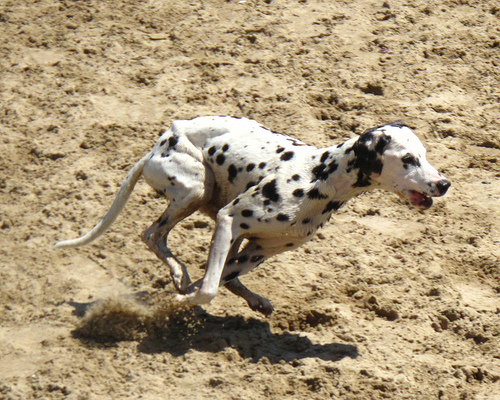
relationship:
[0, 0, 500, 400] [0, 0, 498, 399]
dirt on ground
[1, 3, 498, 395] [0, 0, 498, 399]
dirt on ground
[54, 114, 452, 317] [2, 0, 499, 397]
dog running on sand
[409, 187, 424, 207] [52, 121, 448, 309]
tongue of dog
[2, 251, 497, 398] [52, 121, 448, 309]
sand field under dog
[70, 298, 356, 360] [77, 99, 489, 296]
shadow of dog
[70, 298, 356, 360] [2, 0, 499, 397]
shadow on sand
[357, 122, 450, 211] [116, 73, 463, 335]
head of dog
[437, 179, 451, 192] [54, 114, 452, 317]
nose of dog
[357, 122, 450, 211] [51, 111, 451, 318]
head of dalmation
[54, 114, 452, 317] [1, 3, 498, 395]
dog running in dirt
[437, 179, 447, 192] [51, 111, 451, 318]
nose of dalmation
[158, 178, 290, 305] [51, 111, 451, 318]
leg of dalmation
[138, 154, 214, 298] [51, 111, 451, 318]
leg of dalmation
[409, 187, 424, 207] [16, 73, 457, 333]
tongue of dalmatian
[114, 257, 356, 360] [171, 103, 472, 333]
shadow of dog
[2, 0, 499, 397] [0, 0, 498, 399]
sand covering ground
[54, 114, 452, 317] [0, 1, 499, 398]
dog running on beach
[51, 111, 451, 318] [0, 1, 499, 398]
dalmation running on beach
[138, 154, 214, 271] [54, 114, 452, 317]
leg of running dog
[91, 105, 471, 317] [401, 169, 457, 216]
dog running with open mouth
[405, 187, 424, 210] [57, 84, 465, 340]
tongue of dog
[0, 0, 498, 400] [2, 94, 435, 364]
sand being kicked up by dog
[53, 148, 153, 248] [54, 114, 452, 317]
tail of dog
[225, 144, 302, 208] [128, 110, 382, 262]
black spots on body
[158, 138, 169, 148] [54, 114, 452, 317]
spot on dog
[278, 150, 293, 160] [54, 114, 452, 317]
spot on dog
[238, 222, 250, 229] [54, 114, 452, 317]
spot on dog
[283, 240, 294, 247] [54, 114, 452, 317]
spot on dog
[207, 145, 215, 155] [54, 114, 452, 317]
spot on dog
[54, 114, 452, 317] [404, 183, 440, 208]
dog running with open mouth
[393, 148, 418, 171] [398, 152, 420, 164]
spot over h eye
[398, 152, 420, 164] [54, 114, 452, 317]
eye of dog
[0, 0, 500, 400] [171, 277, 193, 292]
dirt flying from h paw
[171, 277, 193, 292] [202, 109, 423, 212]
paw of dog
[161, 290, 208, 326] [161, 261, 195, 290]
paw touching paw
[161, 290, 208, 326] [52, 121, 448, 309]
paw of dog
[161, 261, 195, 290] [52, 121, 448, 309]
paw of dog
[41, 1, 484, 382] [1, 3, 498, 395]
footprints in dirt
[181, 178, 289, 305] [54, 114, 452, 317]
leg on dog